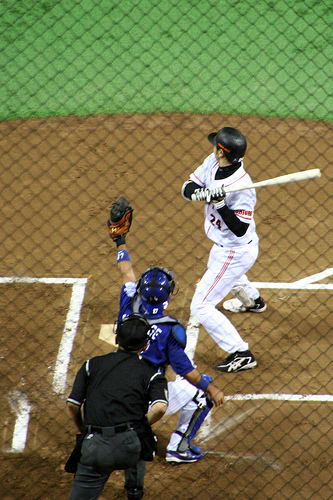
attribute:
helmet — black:
[208, 129, 245, 162]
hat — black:
[116, 313, 150, 349]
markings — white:
[4, 264, 333, 455]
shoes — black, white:
[217, 351, 256, 372]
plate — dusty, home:
[98, 322, 119, 347]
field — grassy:
[2, 3, 333, 126]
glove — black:
[108, 200, 132, 244]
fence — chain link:
[2, 3, 332, 497]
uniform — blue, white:
[117, 269, 215, 465]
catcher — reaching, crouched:
[108, 199, 136, 285]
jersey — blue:
[117, 285, 194, 375]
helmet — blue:
[141, 271, 169, 310]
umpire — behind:
[67, 317, 163, 500]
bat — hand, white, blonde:
[188, 168, 323, 201]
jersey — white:
[188, 151, 256, 244]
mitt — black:
[109, 201, 133, 242]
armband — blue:
[119, 251, 133, 262]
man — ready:
[186, 124, 267, 375]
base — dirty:
[100, 323, 119, 349]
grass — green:
[2, 3, 332, 124]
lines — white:
[0, 265, 332, 451]